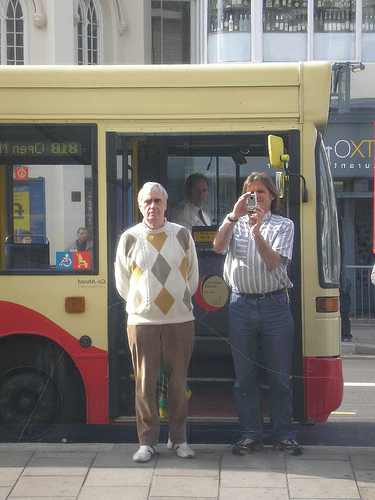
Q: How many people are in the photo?
A: Three.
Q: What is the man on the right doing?
A: Taking a picture.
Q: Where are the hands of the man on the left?
A: Behind his back.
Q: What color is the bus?
A: Red and yellow.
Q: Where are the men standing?
A: In front of the bus.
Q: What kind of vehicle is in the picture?
A: A bus.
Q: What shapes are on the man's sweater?
A: Diamonds.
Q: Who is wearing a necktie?
A: The bus driver.